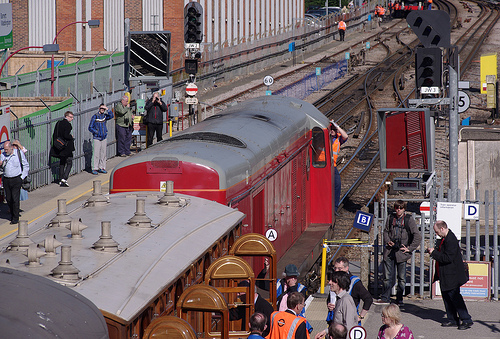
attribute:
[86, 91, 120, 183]
man — standing, train, carrying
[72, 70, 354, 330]
train — arrived, passenger, red, intersecting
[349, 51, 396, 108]
track — railway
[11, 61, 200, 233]
people — waiting, standing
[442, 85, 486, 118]
sign — white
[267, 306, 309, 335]
vest — orange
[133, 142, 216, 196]
engine — red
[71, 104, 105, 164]
fence — metal, blue, gray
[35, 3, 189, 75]
building — brick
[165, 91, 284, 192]
roof — gray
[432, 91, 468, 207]
pole — grey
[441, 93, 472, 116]
letter — black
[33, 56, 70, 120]
pole — red